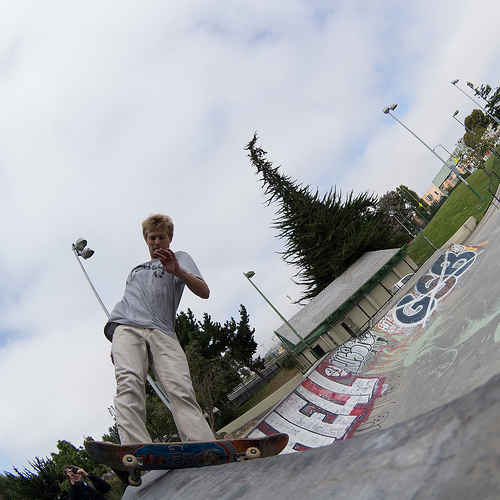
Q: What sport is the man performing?
A: Skateboarding.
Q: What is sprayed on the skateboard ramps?
A: Graffiti.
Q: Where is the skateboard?
A: On the side of the ramp.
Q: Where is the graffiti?
A: On the skateboard ramp.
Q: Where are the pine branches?
A: On the tree.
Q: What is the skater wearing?
A: A t shirt.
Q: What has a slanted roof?
A: On a building.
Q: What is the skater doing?
A: A trick.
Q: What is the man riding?
A: On a skateboard.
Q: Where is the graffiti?
A: At the skate park.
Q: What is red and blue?
A: A skateboard.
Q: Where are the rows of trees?
A: By the skate park.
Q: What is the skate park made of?
A: Cement.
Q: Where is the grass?
A: Beside the skate park.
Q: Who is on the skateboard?
A: A man.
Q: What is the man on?
A: A skateboard.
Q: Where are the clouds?
A: In the sky.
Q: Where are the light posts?
A: In the skate park.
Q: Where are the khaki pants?
A: On the skateboarder.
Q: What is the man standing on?
A: A skate board.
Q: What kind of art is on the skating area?
A: Graffiti.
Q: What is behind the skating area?
A: A building.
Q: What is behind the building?
A: A tree.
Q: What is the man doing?
A: Skateboarding.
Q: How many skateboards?
A: One.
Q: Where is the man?
A: Skate park.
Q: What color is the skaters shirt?
A: Gray.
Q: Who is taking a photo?
A: The man in back.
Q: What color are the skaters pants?
A: Tan.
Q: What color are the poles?
A: Silver.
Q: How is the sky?
A: Cloudy.